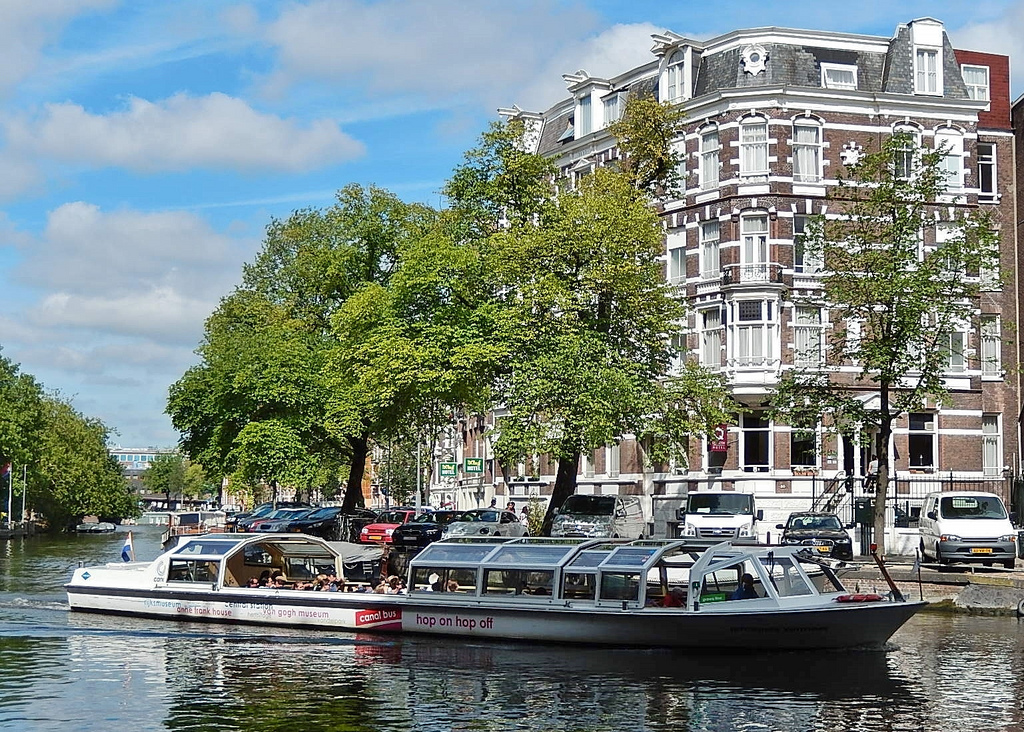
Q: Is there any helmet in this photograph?
A: No, there are no helmets.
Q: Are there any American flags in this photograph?
A: No, there are no American flags.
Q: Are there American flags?
A: No, there are no American flags.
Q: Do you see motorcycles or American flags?
A: No, there are no American flags or motorcycles.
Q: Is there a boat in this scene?
A: Yes, there is a boat.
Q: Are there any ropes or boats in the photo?
A: Yes, there is a boat.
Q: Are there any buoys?
A: No, there are no buoys.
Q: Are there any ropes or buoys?
A: No, there are no buoys or ropes.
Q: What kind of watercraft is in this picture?
A: The watercraft is a boat.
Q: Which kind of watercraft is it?
A: The watercraft is a boat.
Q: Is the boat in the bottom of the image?
A: Yes, the boat is in the bottom of the image.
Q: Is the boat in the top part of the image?
A: No, the boat is in the bottom of the image.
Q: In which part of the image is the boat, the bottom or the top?
A: The boat is in the bottom of the image.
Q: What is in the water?
A: The boat is in the water.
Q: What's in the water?
A: The boat is in the water.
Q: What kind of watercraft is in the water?
A: The watercraft is a boat.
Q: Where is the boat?
A: The boat is in the water.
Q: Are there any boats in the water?
A: Yes, there is a boat in the water.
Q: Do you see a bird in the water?
A: No, there is a boat in the water.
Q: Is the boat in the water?
A: Yes, the boat is in the water.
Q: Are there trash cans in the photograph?
A: No, there are no trash cans.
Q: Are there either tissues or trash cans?
A: No, there are no trash cans or tissues.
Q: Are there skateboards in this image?
A: No, there are no skateboards.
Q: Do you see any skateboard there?
A: No, there are no skateboards.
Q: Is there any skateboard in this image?
A: No, there are no skateboards.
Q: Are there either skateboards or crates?
A: No, there are no skateboards or crates.